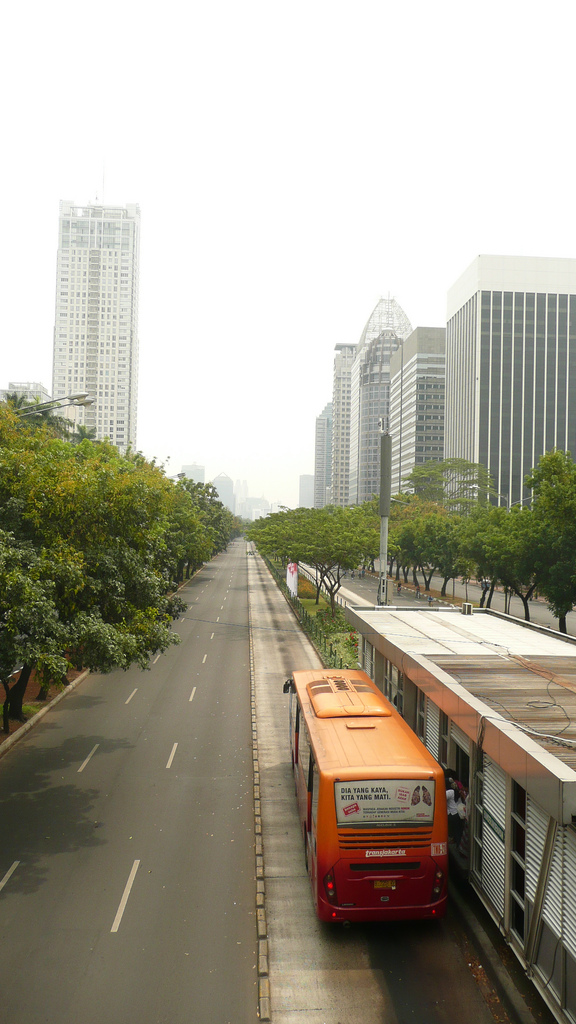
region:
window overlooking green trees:
[416, 381, 427, 392]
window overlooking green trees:
[418, 392, 424, 400]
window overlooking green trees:
[509, 778, 526, 826]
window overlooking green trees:
[508, 813, 525, 863]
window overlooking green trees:
[504, 849, 528, 907]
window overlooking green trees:
[435, 729, 450, 766]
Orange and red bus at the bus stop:
[280, 651, 447, 920]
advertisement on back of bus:
[330, 772, 433, 823]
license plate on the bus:
[373, 875, 396, 890]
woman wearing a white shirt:
[440, 782, 467, 814]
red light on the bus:
[325, 871, 334, 896]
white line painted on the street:
[148, 733, 189, 770]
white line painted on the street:
[104, 850, 154, 931]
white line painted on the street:
[177, 682, 210, 712]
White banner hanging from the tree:
[282, 553, 302, 595]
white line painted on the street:
[116, 683, 157, 721]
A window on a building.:
[418, 380, 427, 391]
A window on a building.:
[415, 392, 425, 401]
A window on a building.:
[420, 402, 425, 410]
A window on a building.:
[416, 412, 425, 419]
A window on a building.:
[415, 422, 422, 431]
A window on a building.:
[416, 431, 420, 440]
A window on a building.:
[415, 455, 422, 462]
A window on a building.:
[378, 394, 387, 402]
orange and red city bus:
[281, 663, 446, 935]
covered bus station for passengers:
[348, 607, 573, 1010]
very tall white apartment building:
[42, 201, 142, 451]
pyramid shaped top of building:
[357, 290, 412, 345]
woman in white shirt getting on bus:
[443, 775, 468, 855]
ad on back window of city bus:
[336, 775, 438, 824]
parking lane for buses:
[250, 547, 533, 1020]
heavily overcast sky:
[3, 0, 574, 497]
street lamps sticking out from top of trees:
[19, 390, 96, 420]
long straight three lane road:
[0, 518, 267, 1021]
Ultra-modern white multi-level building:
[51, 198, 139, 455]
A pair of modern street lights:
[8, 390, 94, 422]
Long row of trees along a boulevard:
[0, 391, 241, 733]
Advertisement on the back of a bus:
[332, 777, 434, 828]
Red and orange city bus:
[284, 668, 443, 921]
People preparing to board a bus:
[445, 767, 465, 845]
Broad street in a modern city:
[3, 533, 259, 1020]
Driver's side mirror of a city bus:
[282, 676, 293, 693]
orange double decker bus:
[283, 656, 453, 937]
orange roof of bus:
[296, 656, 442, 778]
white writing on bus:
[359, 847, 414, 859]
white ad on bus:
[337, 772, 439, 828]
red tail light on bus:
[321, 878, 339, 893]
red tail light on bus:
[328, 906, 337, 920]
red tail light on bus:
[429, 903, 440, 917]